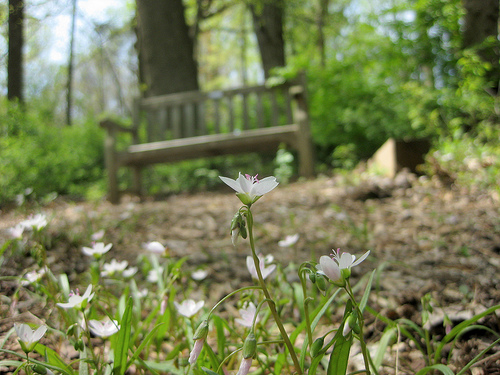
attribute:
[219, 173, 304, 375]
flower — white, small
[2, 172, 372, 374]
flowers — white, small, delicate, tiny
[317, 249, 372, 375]
flower — white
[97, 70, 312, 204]
bench — empty, wood, long, brown, outdoors, outdoor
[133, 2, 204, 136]
trunk — long, brown, large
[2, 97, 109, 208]
leaves — green, overgrown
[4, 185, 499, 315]
ground — brown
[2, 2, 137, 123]
sky — blue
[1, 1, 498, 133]
woods — brown, green, forest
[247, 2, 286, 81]
tree — large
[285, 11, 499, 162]
bushes — green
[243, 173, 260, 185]
center — small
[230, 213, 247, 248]
bud — white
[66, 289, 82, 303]
stamen — pink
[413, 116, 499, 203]
weeds — overgrown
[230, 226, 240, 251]
tip — white